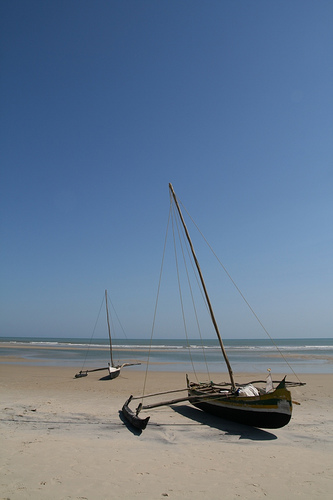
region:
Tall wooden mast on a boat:
[164, 174, 249, 393]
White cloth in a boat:
[239, 384, 258, 397]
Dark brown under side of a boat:
[227, 408, 290, 433]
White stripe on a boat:
[233, 403, 291, 415]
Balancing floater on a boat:
[122, 390, 154, 437]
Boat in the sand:
[122, 372, 326, 447]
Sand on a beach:
[67, 454, 230, 486]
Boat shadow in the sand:
[173, 402, 281, 449]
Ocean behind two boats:
[11, 331, 332, 370]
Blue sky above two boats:
[21, 97, 306, 173]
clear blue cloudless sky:
[97, 18, 303, 126]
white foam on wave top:
[160, 344, 179, 349]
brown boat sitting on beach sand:
[104, 357, 311, 467]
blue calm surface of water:
[280, 338, 325, 345]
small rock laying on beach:
[158, 486, 177, 498]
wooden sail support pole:
[203, 297, 233, 381]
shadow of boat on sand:
[213, 422, 272, 448]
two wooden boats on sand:
[43, 180, 303, 458]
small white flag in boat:
[260, 365, 275, 397]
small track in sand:
[51, 472, 72, 490]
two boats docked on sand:
[62, 174, 304, 434]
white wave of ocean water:
[33, 336, 76, 351]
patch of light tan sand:
[10, 446, 107, 495]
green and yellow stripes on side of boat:
[179, 376, 297, 438]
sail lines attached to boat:
[139, 180, 306, 395]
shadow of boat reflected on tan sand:
[161, 401, 282, 459]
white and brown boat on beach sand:
[98, 361, 132, 382]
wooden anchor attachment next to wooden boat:
[115, 392, 169, 443]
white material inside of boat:
[231, 380, 264, 397]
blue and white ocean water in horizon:
[290, 338, 329, 355]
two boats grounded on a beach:
[62, 178, 317, 461]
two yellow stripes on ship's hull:
[179, 386, 294, 410]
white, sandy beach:
[13, 441, 240, 482]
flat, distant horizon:
[0, 323, 332, 354]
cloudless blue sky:
[33, 201, 136, 264]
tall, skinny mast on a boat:
[101, 284, 116, 361]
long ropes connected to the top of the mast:
[135, 169, 298, 404]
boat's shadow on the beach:
[162, 397, 275, 447]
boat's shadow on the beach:
[95, 371, 109, 379]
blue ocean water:
[235, 338, 324, 349]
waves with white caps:
[39, 339, 81, 348]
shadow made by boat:
[173, 395, 271, 456]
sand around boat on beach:
[171, 416, 255, 481]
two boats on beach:
[58, 331, 294, 449]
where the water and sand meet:
[156, 365, 179, 378]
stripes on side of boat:
[232, 390, 295, 418]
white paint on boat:
[107, 365, 123, 373]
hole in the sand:
[157, 484, 179, 498]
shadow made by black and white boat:
[97, 368, 123, 382]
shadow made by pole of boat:
[4, 409, 105, 429]